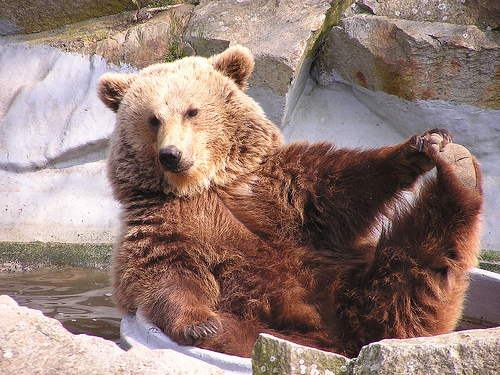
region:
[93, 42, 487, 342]
brown furry bear resting on back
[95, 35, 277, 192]
furry bear face with black eyes and black nose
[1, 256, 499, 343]
muddy water behind reclining bear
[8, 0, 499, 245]
wall of large rocks in bear's enclave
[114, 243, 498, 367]
round cement tub reclining bear is sitting in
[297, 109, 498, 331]
bear touching left paw to leaft foot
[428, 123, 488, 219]
bear foot underside with claws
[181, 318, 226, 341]
brown pointy claws of bear's left hand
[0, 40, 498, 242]
portion of gray rocks painted white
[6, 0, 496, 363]
sunny outdoor day scene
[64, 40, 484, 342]
brown grizzly bear laying down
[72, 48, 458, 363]
large bear sitting down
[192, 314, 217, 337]
claws on paws of bear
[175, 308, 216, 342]
large paws of bear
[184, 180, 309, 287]
brown bushy fur on bear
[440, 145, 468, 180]
large brown foot of bear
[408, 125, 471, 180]
bear hand grabbing foot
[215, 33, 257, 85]
large furry ear of bear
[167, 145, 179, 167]
black snout of bear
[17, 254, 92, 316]
water behind bear sitting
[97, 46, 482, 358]
a bear enjoying the day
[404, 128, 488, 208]
a paw touching his foot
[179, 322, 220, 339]
bear claws on a bear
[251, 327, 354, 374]
a rock beside the pool of water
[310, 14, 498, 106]
a large rock above the water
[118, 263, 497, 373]
a tub containing the bear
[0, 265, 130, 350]
dirty water behind the bear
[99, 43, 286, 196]
the furry head of a bear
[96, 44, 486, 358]
brown bear who is relaxing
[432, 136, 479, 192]
the sole of a back paw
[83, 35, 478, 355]
Brown bear in the water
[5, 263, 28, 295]
Small ripples in the water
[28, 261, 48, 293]
Small ripples in the water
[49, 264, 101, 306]
Small ripples in the water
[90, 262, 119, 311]
Small ripples in the water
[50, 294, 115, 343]
Small ripples in the water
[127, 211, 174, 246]
Dark brown fur on animal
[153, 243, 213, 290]
Dark brown fur on animal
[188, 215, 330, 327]
Dark brown fur on animal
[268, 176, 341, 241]
Dark brown fur on animal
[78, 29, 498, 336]
Small brown beat in water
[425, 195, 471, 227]
Small patch of brown hair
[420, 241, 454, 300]
Small patch of brown hair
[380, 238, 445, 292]
Small patch of brown hair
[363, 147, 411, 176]
Small patch of brown hair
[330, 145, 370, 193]
Small patch of brown hair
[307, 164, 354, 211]
Small patch of brown hair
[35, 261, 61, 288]
Small ripples in the water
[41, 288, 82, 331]
Small ripples in the water